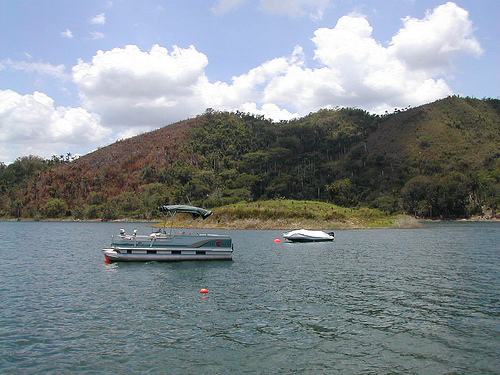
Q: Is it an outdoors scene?
A: Yes, it is outdoors.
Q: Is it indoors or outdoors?
A: It is outdoors.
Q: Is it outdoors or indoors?
A: It is outdoors.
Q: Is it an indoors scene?
A: No, it is outdoors.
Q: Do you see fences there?
A: No, there are no fences.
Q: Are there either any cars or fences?
A: No, there are no fences or cars.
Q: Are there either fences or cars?
A: No, there are no fences or cars.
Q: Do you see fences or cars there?
A: No, there are no fences or cars.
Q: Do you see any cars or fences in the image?
A: No, there are no fences or cars.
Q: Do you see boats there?
A: Yes, there is a boat.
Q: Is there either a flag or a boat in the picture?
A: Yes, there is a boat.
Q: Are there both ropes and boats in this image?
A: No, there is a boat but no ropes.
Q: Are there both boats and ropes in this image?
A: No, there is a boat but no ropes.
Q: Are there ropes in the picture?
A: No, there are no ropes.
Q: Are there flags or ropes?
A: No, there are no ropes or flags.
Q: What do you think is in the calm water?
A: The boat is in the water.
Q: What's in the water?
A: The boat is in the water.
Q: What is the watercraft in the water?
A: The watercraft is a boat.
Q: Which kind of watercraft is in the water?
A: The watercraft is a boat.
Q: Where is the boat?
A: The boat is in the water.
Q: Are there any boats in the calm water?
A: Yes, there is a boat in the water.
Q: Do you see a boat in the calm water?
A: Yes, there is a boat in the water.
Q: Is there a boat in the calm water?
A: Yes, there is a boat in the water.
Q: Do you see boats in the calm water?
A: Yes, there is a boat in the water.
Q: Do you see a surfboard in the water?
A: No, there is a boat in the water.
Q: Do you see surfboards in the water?
A: No, there is a boat in the water.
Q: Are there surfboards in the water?
A: No, there is a boat in the water.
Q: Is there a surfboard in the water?
A: No, there is a boat in the water.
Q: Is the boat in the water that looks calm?
A: Yes, the boat is in the water.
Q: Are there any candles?
A: No, there are no candles.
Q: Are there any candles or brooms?
A: No, there are no candles or brooms.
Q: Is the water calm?
A: Yes, the water is calm.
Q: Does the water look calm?
A: Yes, the water is calm.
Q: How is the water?
A: The water is calm.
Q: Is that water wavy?
A: No, the water is calm.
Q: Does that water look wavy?
A: No, the water is calm.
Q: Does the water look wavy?
A: No, the water is calm.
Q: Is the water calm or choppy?
A: The water is calm.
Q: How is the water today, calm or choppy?
A: The water is calm.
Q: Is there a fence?
A: No, there are no fences.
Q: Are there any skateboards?
A: No, there are no skateboards.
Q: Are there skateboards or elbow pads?
A: No, there are no skateboards or elbow pads.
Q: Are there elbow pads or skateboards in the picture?
A: No, there are no skateboards or elbow pads.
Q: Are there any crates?
A: No, there are no crates.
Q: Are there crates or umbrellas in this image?
A: No, there are no crates or umbrellas.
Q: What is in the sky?
A: The clouds are in the sky.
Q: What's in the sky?
A: The clouds are in the sky.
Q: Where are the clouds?
A: The clouds are in the sky.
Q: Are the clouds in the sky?
A: Yes, the clouds are in the sky.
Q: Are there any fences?
A: No, there are no fences.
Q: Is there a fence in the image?
A: No, there are no fences.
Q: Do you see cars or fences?
A: No, there are no fences or cars.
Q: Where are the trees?
A: The trees are on the hills.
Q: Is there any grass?
A: Yes, there is grass.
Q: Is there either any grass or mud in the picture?
A: Yes, there is grass.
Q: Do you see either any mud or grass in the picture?
A: Yes, there is grass.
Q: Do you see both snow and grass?
A: No, there is grass but no snow.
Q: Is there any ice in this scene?
A: No, there is no ice.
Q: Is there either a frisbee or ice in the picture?
A: No, there are no ice or frisbees.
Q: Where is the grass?
A: The grass is on the hills.